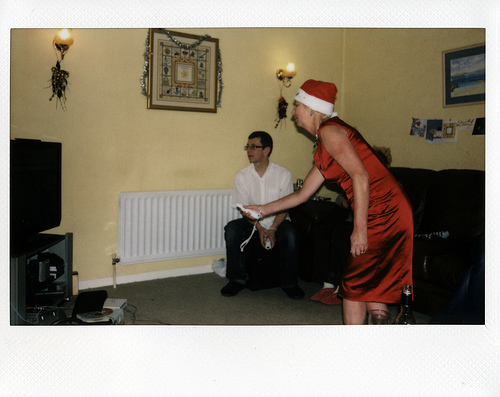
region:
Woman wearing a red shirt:
[282, 72, 439, 329]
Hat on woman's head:
[291, 65, 347, 117]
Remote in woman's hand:
[230, 201, 270, 241]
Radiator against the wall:
[107, 180, 249, 272]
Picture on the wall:
[137, 28, 239, 123]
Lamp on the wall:
[262, 50, 306, 97]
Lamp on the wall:
[45, 31, 89, 61]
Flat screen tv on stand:
[5, 127, 90, 327]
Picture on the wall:
[426, 39, 493, 119]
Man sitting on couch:
[213, 122, 310, 301]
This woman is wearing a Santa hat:
[303, 78, 321, 115]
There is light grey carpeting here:
[195, 275, 208, 312]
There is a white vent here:
[118, 207, 164, 292]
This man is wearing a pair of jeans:
[222, 232, 253, 313]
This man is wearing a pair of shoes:
[221, 278, 243, 304]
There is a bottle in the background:
[398, 288, 412, 333]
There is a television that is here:
[9, 126, 42, 233]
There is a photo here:
[149, 33, 220, 148]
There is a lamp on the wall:
[281, 59, 298, 91]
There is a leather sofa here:
[433, 180, 451, 221]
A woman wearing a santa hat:
[207, 63, 417, 326]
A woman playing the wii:
[222, 76, 426, 332]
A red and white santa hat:
[293, 70, 345, 122]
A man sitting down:
[207, 118, 304, 303]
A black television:
[12, 133, 72, 253]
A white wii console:
[97, 293, 134, 315]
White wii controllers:
[233, 198, 275, 253]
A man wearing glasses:
[223, 129, 304, 299]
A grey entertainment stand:
[15, 226, 75, 313]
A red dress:
[310, 113, 426, 308]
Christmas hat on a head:
[295, 76, 339, 117]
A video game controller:
[235, 200, 261, 250]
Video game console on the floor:
[102, 295, 128, 309]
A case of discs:
[71, 288, 113, 328]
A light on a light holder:
[48, 30, 73, 102]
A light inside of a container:
[275, 60, 300, 130]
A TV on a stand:
[0, 135, 65, 250]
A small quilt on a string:
[406, 115, 428, 136]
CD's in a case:
[72, 287, 114, 327]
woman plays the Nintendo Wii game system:
[235, 76, 417, 323]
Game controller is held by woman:
[231, 201, 263, 253]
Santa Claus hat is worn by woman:
[292, 79, 339, 116]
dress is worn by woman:
[307, 117, 415, 305]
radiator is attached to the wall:
[113, 188, 245, 274]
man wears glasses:
[220, 129, 291, 301]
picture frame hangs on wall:
[140, 32, 223, 111]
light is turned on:
[53, 27, 76, 57]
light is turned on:
[276, 57, 297, 79]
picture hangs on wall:
[437, 41, 485, 106]